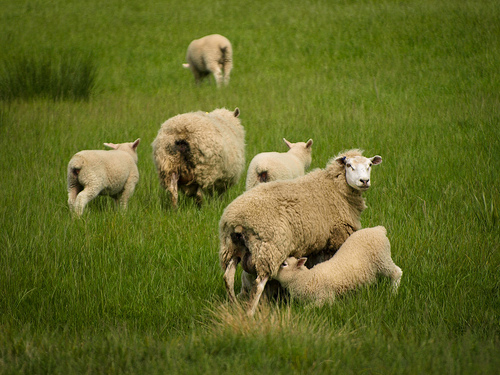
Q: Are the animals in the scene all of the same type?
A: Yes, all the animals are sheep.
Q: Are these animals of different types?
A: No, all the animals are sheep.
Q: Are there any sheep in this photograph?
A: Yes, there is a sheep.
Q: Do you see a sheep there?
A: Yes, there is a sheep.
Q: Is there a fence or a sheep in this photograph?
A: Yes, there is a sheep.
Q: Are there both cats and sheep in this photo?
A: No, there is a sheep but no cats.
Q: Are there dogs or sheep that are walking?
A: Yes, the sheep is walking.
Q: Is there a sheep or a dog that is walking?
A: Yes, the sheep is walking.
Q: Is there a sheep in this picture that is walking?
A: Yes, there is a sheep that is walking.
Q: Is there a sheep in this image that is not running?
A: Yes, there is a sheep that is walking.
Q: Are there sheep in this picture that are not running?
A: Yes, there is a sheep that is walking.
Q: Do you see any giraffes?
A: No, there are no giraffes.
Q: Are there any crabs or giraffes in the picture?
A: No, there are no giraffes or crabs.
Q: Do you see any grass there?
A: Yes, there is grass.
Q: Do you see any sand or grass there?
A: Yes, there is grass.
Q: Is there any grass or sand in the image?
A: Yes, there is grass.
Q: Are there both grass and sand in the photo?
A: No, there is grass but no sand.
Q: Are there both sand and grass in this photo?
A: No, there is grass but no sand.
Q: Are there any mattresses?
A: No, there are no mattresses.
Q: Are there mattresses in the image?
A: No, there are no mattresses.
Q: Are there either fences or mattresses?
A: No, there are no mattresses or fences.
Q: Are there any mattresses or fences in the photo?
A: No, there are no mattresses or fences.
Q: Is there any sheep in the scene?
A: Yes, there is a sheep.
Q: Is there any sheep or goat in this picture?
A: Yes, there is a sheep.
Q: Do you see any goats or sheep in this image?
A: Yes, there is a sheep.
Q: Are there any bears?
A: No, there are no bears.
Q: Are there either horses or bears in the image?
A: No, there are no bears or horses.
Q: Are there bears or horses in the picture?
A: No, there are no bears or horses.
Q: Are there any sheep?
A: Yes, there is a sheep.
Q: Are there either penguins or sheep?
A: Yes, there is a sheep.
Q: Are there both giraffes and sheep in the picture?
A: No, there is a sheep but no giraffes.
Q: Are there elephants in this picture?
A: No, there are no elephants.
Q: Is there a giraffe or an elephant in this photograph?
A: No, there are no elephants or giraffes.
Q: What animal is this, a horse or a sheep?
A: This is a sheep.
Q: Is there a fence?
A: No, there are no fences.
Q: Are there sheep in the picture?
A: Yes, there is a sheep.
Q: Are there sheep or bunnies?
A: Yes, there is a sheep.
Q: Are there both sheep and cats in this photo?
A: No, there is a sheep but no cats.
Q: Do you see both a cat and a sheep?
A: No, there is a sheep but no cats.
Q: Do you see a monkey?
A: No, there are no monkeys.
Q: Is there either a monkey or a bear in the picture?
A: No, there are no monkeys or bears.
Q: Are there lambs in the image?
A: Yes, there is a lamb.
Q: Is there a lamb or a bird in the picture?
A: Yes, there is a lamb.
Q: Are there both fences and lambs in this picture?
A: No, there is a lamb but no fences.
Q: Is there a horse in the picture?
A: No, there are no horses.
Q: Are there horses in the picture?
A: No, there are no horses.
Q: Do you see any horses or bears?
A: No, there are no horses or bears.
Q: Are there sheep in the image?
A: Yes, there is a sheep.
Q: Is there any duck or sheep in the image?
A: Yes, there is a sheep.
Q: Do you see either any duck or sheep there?
A: Yes, there is a sheep.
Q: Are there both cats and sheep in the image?
A: No, there is a sheep but no cats.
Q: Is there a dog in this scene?
A: No, there are no dogs.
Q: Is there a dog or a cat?
A: No, there are no dogs or cats.